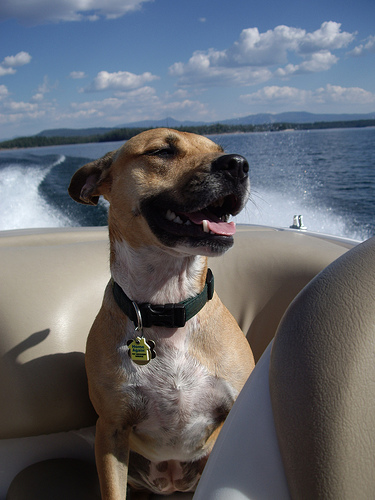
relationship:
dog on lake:
[56, 96, 281, 461] [2, 82, 359, 261]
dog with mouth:
[56, 96, 281, 461] [150, 166, 253, 254]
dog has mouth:
[56, 96, 281, 461] [150, 166, 253, 254]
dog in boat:
[56, 96, 281, 461] [1, 140, 348, 409]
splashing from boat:
[257, 159, 349, 222] [1, 140, 348, 409]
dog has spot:
[56, 96, 281, 461] [143, 290, 224, 410]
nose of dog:
[187, 144, 253, 189] [56, 96, 281, 461]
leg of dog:
[75, 382, 142, 498] [56, 96, 281, 461]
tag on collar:
[111, 326, 155, 371] [71, 234, 245, 343]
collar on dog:
[71, 234, 245, 343] [56, 96, 281, 461]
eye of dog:
[136, 121, 197, 169] [56, 96, 281, 461]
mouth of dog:
[150, 166, 253, 254] [56, 96, 281, 461]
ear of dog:
[35, 152, 125, 208] [56, 96, 281, 461]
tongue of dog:
[143, 194, 261, 267] [56, 96, 281, 461]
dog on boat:
[56, 96, 281, 461] [1, 140, 348, 409]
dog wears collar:
[56, 96, 281, 461] [71, 234, 245, 343]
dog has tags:
[56, 96, 281, 461] [60, 262, 243, 374]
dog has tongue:
[56, 96, 281, 461] [143, 194, 261, 267]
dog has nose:
[56, 96, 281, 461] [187, 144, 253, 189]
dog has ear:
[56, 96, 281, 461] [35, 152, 125, 208]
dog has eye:
[56, 96, 281, 461] [136, 121, 197, 169]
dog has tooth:
[56, 96, 281, 461] [176, 206, 223, 261]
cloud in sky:
[201, 19, 326, 100] [102, 13, 296, 98]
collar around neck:
[71, 234, 245, 343] [63, 212, 263, 319]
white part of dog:
[115, 247, 199, 301] [56, 96, 281, 461]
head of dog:
[46, 89, 290, 289] [56, 96, 281, 461]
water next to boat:
[285, 144, 339, 213] [1, 140, 348, 409]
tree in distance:
[19, 86, 159, 152] [2, 82, 359, 261]